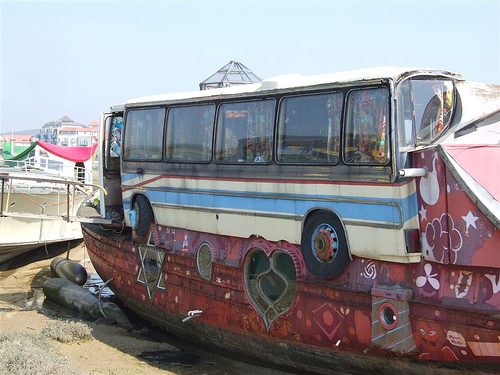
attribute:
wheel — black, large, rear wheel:
[300, 209, 348, 277]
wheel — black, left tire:
[131, 195, 150, 235]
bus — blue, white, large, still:
[98, 67, 464, 275]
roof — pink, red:
[37, 140, 98, 164]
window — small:
[48, 159, 64, 172]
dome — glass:
[199, 59, 262, 91]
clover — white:
[414, 262, 440, 290]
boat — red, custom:
[80, 67, 498, 373]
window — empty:
[276, 94, 345, 164]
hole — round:
[378, 302, 398, 328]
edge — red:
[377, 302, 399, 329]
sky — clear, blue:
[2, 2, 500, 132]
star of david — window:
[134, 231, 167, 306]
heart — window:
[241, 245, 300, 335]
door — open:
[101, 113, 126, 221]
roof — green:
[6, 142, 38, 168]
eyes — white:
[418, 328, 435, 338]